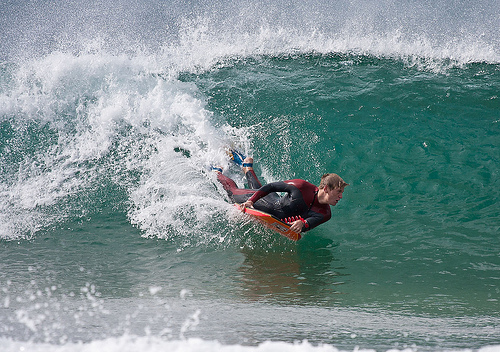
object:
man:
[187, 148, 350, 234]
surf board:
[233, 200, 305, 245]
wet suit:
[213, 172, 333, 230]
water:
[0, 37, 499, 351]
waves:
[0, 0, 499, 249]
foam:
[0, 0, 499, 250]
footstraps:
[207, 161, 225, 173]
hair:
[317, 173, 350, 190]